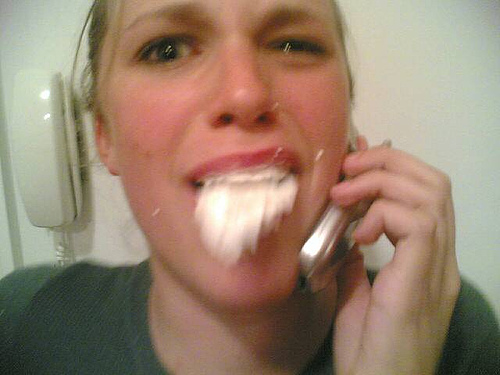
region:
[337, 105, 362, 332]
This woman is holding a cellphone to her ear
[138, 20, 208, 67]
This woman has dark green eyes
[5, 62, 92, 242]
There is a phone that is on the wall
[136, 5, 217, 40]
There is an eyebrow that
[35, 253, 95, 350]
The woman is wearing a grey t-shirt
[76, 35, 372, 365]
This photo was taken in the city of Dayton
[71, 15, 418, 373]
This photo was taken in the state of Ohio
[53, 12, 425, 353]
Jackson Mingus is the man who took this photo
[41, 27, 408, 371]
This woman's name is Lydia Johnson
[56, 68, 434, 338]
This woman is a student in college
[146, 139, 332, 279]
a woman with white stuff in her mouth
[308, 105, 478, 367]
a silver cellphone in hand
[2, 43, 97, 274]
white phone hanging on wall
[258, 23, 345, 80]
One eye squinted and almost shut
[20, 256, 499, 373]
a green shirt worn by a woman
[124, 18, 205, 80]
One eye completely open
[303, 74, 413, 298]
a cellphone held to her ear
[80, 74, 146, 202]
One ear is visible on woman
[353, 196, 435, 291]
Pinky finger is curled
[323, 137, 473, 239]
two fingers are on the phone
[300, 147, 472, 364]
Girl holding silver phone in left hand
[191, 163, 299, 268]
White foam coming out of woman's mouth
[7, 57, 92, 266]
White phone on wall behind woman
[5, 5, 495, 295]
White wall behind woman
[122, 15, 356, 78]
The woman's eyes are open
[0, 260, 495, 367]
The woman is wearing a green shirt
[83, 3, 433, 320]
The woman is facing the camera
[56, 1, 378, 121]
The woman's hair is pulled back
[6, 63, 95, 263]
White phone isn't in use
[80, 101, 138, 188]
One ear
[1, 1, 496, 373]
Woman is in the foreground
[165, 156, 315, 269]
Woman has food in her mouth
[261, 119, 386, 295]
Woman is holding a cell phone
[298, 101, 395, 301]
Cell phone is silver colored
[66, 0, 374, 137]
Woman has blonde hair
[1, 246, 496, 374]
Woman is wearing a green shirt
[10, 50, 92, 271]
A homep hone is behind the woman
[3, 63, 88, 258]
The home phone is white in color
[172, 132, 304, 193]
Woman is wearing lipstick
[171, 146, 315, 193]
Lipstick is red in color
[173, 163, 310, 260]
white stuff in girl's mouth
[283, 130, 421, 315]
phone in girl's hand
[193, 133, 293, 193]
lips of the girl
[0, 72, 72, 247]
phone in the background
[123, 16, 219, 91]
eye of the girl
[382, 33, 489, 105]
white background of photo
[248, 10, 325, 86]
left eye of person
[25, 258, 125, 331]
shoulder of the person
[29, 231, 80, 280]
wire of the phone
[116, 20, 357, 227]
girl looking at the camera